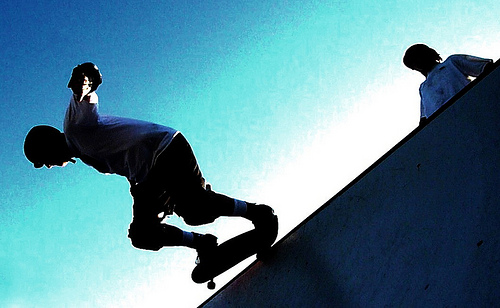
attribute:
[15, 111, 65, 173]
helmet — dark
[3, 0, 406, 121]
sky — blue and white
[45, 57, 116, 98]
pad — for elbow, skateboarder's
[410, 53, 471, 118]
shirt — white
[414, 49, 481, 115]
shirt — white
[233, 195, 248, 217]
sock — white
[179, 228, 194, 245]
sock — white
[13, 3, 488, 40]
sky — bright blue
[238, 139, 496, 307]
ramp — cement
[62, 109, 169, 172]
t-shirt — white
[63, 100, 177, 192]
shirt — short sleeve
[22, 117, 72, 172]
helmet — dark